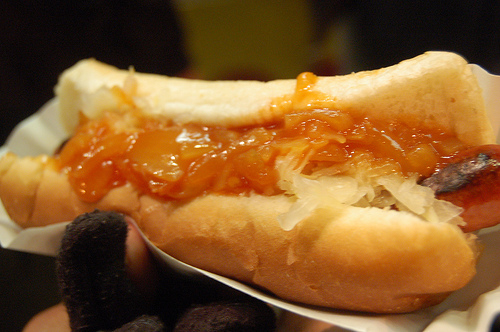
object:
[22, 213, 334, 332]
person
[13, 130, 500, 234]
hot dog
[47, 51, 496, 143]
bread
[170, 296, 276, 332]
gloves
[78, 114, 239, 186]
sauce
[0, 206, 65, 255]
paper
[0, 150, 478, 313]
bun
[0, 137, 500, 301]
half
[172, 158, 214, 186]
pieces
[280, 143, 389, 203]
sauerkraut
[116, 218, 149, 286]
finger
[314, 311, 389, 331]
piece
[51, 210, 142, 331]
glove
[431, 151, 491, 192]
spot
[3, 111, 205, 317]
wrapper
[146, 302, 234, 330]
part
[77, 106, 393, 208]
toppings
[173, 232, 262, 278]
crust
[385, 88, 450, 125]
inside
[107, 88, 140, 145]
onions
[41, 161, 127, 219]
side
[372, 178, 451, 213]
shreds